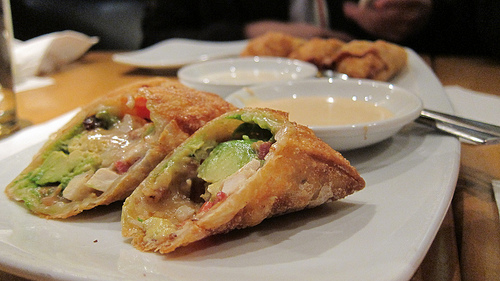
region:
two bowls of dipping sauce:
[179, 45, 396, 122]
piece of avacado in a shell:
[7, 143, 107, 183]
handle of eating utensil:
[414, 87, 499, 149]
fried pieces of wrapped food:
[235, 19, 408, 76]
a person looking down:
[330, 0, 425, 37]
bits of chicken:
[57, 162, 124, 199]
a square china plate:
[111, 35, 250, 72]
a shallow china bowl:
[226, 73, 425, 144]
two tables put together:
[420, 50, 468, 280]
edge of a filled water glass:
[0, 0, 19, 139]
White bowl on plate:
[212, 80, 422, 154]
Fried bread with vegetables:
[103, 100, 355, 257]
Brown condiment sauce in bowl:
[255, 93, 388, 131]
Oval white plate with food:
[4, 42, 461, 279]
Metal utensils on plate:
[406, 96, 495, 150]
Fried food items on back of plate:
[243, 28, 411, 84]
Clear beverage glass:
[0, 1, 20, 136]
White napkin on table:
[442, 82, 498, 153]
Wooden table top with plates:
[13, 43, 495, 276]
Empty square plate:
[111, 32, 252, 70]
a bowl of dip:
[226, 77, 421, 150]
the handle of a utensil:
[416, 108, 496, 141]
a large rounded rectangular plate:
[0, 40, 451, 275]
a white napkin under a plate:
[440, 80, 495, 131]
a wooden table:
[0, 0, 495, 275]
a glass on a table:
[0, 0, 19, 139]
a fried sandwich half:
[120, 106, 368, 257]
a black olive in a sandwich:
[81, 113, 111, 127]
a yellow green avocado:
[30, 145, 102, 186]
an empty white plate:
[110, 34, 252, 69]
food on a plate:
[34, 29, 499, 273]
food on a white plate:
[32, 25, 296, 260]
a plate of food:
[0, 33, 380, 278]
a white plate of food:
[48, 12, 436, 279]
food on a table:
[80, 72, 447, 276]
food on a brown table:
[27, 51, 472, 275]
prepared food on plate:
[61, 33, 471, 274]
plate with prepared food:
[27, 23, 393, 264]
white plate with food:
[4, 23, 347, 273]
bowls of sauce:
[212, 20, 447, 190]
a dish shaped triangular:
[5, 20, 466, 280]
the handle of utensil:
[428, 102, 498, 152]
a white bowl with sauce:
[233, 73, 427, 151]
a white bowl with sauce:
[172, 45, 319, 92]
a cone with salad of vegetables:
[119, 100, 370, 257]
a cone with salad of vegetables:
[5, 64, 179, 214]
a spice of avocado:
[194, 130, 264, 177]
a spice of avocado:
[33, 148, 69, 190]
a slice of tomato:
[112, 90, 157, 126]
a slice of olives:
[223, 115, 271, 147]